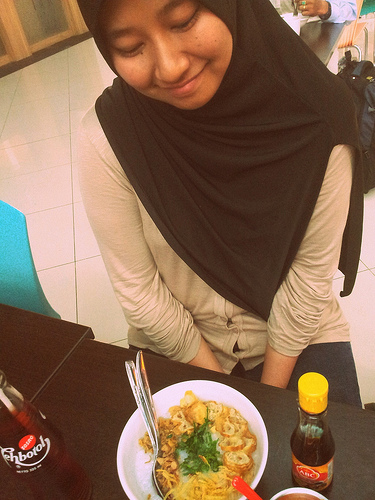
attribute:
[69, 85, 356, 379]
shirt — Brown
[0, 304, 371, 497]
black table — Black 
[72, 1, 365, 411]
girl — Smiling 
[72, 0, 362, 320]
burka — Blue 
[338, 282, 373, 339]
tile — Tan 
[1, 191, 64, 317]
empty chair — blue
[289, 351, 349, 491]
bottle — Glass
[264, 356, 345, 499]
bottle — Maroon 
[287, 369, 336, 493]
bottle — brown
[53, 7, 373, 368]
woman — Smiling 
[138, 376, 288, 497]
food — white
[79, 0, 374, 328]
cover — Black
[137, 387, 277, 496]
vegetables — Green 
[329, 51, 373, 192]
backpack — blue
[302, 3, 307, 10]
ring — Golden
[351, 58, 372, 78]
handle — Black 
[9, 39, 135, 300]
tiles — White 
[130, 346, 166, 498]
cuttler — Silver 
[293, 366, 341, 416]
bottle top — Yellow 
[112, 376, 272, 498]
plate — White 